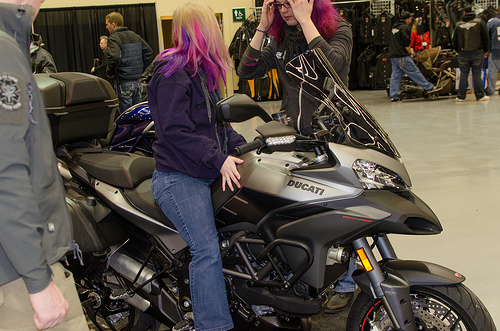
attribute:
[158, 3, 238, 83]
hair — purple, pink, long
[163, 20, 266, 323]
girl — purple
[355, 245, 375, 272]
street sign — yellow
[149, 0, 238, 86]
hair — purple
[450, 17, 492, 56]
jacket — Harley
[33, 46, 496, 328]
motorcycle — Ducati, black, silver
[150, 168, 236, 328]
jeans — light blue, women's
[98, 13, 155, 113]
man — drinking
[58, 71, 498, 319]
motorcycle — Ducati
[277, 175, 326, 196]
logo — small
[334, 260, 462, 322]
tire — front tire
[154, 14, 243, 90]
hair — pink